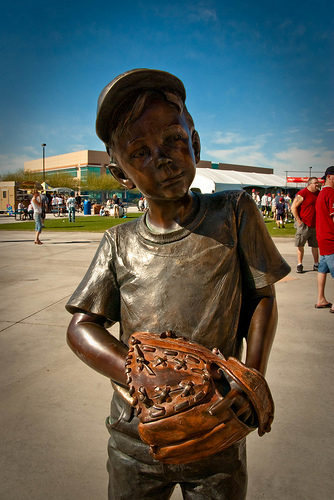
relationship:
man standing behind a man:
[313, 165, 333, 312] [289, 175, 322, 273]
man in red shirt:
[278, 170, 322, 279] [293, 191, 322, 226]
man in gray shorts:
[278, 170, 322, 279] [294, 219, 320, 250]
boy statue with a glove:
[66, 66, 290, 500] [125, 329, 275, 462]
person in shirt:
[31, 189, 44, 244] [31, 196, 42, 215]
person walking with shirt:
[31, 189, 44, 241] [28, 193, 46, 213]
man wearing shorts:
[290, 176, 322, 273] [294, 220, 318, 249]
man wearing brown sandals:
[313, 165, 333, 312] [315, 298, 332, 312]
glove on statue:
[125, 327, 276, 467] [45, 44, 295, 487]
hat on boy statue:
[85, 62, 199, 151] [66, 66, 290, 500]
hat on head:
[85, 62, 199, 151] [89, 63, 210, 203]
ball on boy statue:
[131, 339, 275, 453] [66, 66, 290, 500]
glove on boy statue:
[115, 323, 293, 470] [66, 66, 290, 500]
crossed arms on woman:
[35, 192, 43, 212] [13, 171, 61, 254]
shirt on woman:
[29, 194, 43, 212] [13, 171, 61, 254]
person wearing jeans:
[31, 189, 44, 244] [76, 358, 283, 498]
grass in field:
[80, 225, 97, 237] [36, 208, 103, 247]